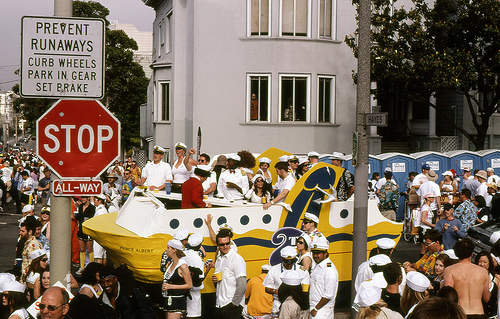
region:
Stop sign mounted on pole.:
[34, 93, 123, 178]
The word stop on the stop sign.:
[45, 120, 110, 165]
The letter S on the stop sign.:
[43, 119, 64, 156]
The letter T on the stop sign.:
[58, 118, 77, 154]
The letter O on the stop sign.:
[77, 119, 96, 154]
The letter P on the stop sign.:
[95, 123, 114, 155]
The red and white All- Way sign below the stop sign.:
[48, 176, 103, 196]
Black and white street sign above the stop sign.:
[22, 14, 104, 103]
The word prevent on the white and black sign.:
[31, 19, 95, 36]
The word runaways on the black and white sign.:
[28, 36, 95, 56]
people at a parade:
[6, 6, 491, 311]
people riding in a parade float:
[18, 6, 497, 307]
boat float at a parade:
[85, 115, 426, 293]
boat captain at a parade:
[139, 121, 206, 198]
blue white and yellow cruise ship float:
[77, 147, 438, 292]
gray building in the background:
[8, 1, 498, 288]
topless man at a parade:
[433, 229, 498, 316]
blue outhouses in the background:
[262, 146, 495, 187]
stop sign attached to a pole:
[12, 91, 147, 216]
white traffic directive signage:
[12, 14, 113, 101]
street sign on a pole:
[354, 106, 389, 133]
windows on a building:
[225, 58, 350, 139]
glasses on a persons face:
[212, 229, 234, 255]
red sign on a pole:
[29, 87, 128, 206]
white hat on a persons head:
[148, 141, 167, 165]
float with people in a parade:
[84, 141, 411, 301]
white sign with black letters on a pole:
[11, 8, 115, 104]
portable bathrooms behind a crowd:
[373, 141, 498, 201]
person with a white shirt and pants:
[303, 236, 340, 317]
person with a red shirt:
[175, 158, 217, 213]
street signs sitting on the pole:
[20, 15, 123, 202]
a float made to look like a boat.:
[81, 163, 405, 305]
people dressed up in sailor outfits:
[138, 148, 265, 208]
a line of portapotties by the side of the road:
[322, 149, 496, 193]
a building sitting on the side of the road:
[138, 2, 378, 155]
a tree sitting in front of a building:
[375, 5, 498, 148]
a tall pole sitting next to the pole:
[343, 5, 374, 290]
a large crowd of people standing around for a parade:
[21, 140, 497, 313]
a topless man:
[435, 237, 489, 317]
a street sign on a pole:
[358, 112, 388, 129]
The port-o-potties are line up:
[208, 147, 498, 226]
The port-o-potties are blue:
[210, 150, 499, 222]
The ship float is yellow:
[83, 147, 412, 298]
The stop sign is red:
[33, 92, 124, 179]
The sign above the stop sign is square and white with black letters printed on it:
[19, 12, 107, 99]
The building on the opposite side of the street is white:
[130, 2, 499, 172]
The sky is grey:
[2, 0, 158, 97]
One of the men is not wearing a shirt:
[437, 234, 499, 316]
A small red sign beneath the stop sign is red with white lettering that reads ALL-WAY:
[51, 176, 106, 198]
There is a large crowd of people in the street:
[3, 142, 499, 317]